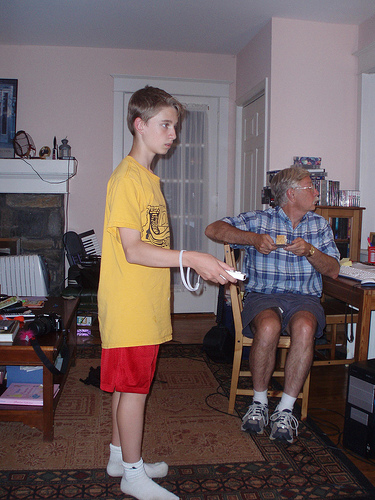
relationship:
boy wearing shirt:
[96, 84, 237, 500] [100, 154, 172, 346]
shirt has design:
[100, 154, 172, 346] [143, 206, 177, 248]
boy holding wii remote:
[96, 84, 237, 500] [220, 267, 250, 281]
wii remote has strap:
[220, 267, 250, 281] [176, 246, 201, 292]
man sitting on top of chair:
[204, 162, 338, 440] [220, 243, 311, 421]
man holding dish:
[204, 162, 338, 440] [265, 242, 297, 253]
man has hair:
[204, 162, 338, 440] [264, 168, 303, 199]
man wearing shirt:
[204, 162, 338, 440] [226, 207, 336, 295]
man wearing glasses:
[204, 162, 338, 440] [296, 176, 319, 195]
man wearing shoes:
[204, 162, 338, 440] [247, 405, 291, 437]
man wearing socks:
[204, 162, 338, 440] [252, 390, 297, 409]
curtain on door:
[148, 108, 206, 253] [113, 81, 219, 267]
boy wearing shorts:
[96, 84, 237, 500] [102, 343, 153, 396]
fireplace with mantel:
[3, 192, 66, 307] [3, 156, 82, 196]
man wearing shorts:
[204, 162, 338, 440] [239, 286, 322, 335]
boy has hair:
[96, 84, 237, 500] [122, 82, 185, 117]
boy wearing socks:
[96, 84, 237, 500] [106, 449, 179, 500]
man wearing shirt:
[204, 162, 338, 440] [100, 154, 172, 346]